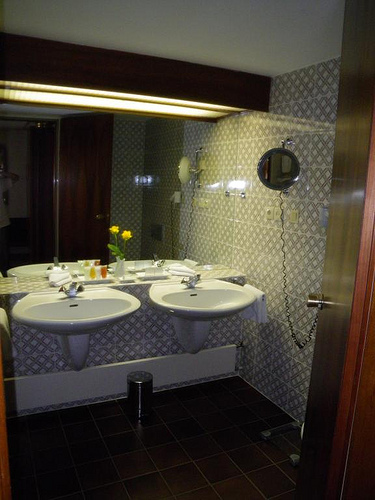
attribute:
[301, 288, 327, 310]
handle — door handle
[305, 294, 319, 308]
knob — shiny, silver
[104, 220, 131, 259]
flower — yellow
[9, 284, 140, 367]
sink — white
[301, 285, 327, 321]
knob — wooden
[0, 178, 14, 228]
shirt — white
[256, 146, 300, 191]
mirror — Circular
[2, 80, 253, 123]
light — large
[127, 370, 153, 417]
trash can — silver, Small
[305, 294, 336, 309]
door handle — silver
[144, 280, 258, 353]
sink — White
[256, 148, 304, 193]
mirror — round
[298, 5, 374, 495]
door — tall, wooden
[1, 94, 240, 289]
mirror — large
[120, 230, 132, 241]
flower — yellow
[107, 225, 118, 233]
flower — yellow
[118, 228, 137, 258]
flower — yellow